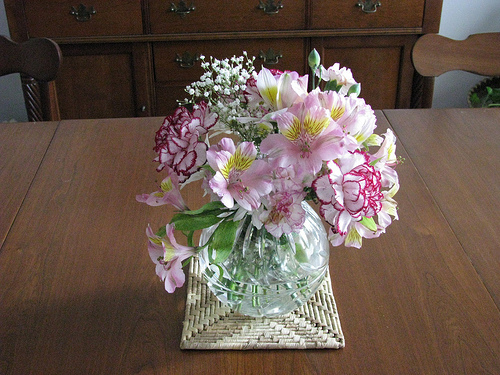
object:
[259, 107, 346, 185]
flowers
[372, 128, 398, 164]
flowers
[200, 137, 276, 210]
flowers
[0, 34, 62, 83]
chair back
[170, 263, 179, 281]
pink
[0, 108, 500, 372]
board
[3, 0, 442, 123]
cabinet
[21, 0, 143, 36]
drawer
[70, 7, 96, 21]
handle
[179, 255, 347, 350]
mat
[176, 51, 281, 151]
flowers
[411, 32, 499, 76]
chair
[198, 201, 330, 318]
vase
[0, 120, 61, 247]
crack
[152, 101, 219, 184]
flower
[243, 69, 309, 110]
flower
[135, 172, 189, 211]
flowers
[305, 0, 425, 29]
drawer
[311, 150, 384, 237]
flower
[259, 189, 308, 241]
flower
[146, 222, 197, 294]
flower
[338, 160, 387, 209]
tips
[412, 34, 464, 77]
tops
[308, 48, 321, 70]
flowers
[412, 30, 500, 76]
back